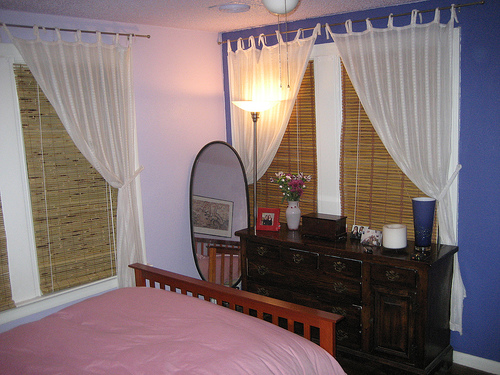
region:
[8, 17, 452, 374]
a bedroom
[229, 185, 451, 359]
a dresser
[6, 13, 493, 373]
neat and tidy bedroom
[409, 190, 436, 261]
a purple flower vase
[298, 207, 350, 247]
a jewelry box on top of a dresser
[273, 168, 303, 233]
a flower vase with flowers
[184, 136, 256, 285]
a free standing mirror in the corner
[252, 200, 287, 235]
a picture frame on top of a dresser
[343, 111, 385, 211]
a window blinds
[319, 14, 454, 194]
a white curtain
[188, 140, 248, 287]
a mirror in a corner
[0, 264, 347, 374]
a bed with a pink comforter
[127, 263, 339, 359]
a wooden bed end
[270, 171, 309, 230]
a vase with flowers in it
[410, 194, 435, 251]
a blue vase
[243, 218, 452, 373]
a dark wooden chest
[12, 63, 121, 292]
thin wooden blinds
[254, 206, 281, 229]
picture in a red frame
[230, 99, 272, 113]
glass housing for a bulb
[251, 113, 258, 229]
a metal lamp post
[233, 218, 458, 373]
a wooden dresser in a bedroom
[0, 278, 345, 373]
pink cover-bed on a bed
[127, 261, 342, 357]
the wooden foot of a bed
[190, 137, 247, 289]
a standing oval mirror in a bedroom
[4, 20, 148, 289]
white drapes on a window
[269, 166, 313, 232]
colorful flowers in a white pot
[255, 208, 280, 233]
a red picture frame on a dresser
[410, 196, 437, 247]
a blue large cup on a dresser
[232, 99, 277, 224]
a standing lamp in a bedroom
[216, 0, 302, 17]
white light fixtures on a ceiling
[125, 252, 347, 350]
Wooden footboard of bed.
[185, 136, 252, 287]
Oval mirror in bedroom.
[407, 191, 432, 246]
Purple vase on dresser.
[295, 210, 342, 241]
Wooden box on dresser.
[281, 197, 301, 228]
White vase on dresser.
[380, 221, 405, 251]
White candle of dresser.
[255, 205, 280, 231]
Photo in red frame on dresser.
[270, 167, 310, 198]
Purple and pink flowers.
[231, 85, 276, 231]
White floor lamp with metal pole.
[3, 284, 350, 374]
Pink blanket on bed.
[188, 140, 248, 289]
a round oval mirror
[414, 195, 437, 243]
a tall blue and white vase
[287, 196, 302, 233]
a white ceramic vase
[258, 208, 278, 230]
a red photo frame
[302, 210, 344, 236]
a dark wooden jewelry box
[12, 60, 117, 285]
long wooden window blinds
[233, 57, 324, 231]
the white leg of a cowlong wooden window blinds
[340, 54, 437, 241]
long wooden window blinds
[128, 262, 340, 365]
a medium wooden foot board of a bed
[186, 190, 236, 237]
a photo hanging on the wall